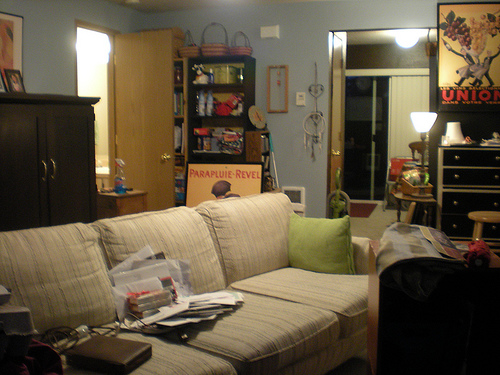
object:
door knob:
[161, 153, 171, 162]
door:
[113, 27, 175, 215]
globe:
[393, 37, 418, 47]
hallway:
[319, 27, 437, 215]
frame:
[3, 65, 26, 93]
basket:
[177, 29, 201, 57]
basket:
[199, 21, 230, 60]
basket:
[228, 30, 252, 56]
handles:
[37, 158, 57, 183]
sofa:
[0, 192, 417, 375]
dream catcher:
[301, 58, 325, 159]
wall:
[131, 1, 441, 213]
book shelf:
[184, 56, 255, 174]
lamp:
[408, 108, 440, 198]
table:
[391, 191, 438, 235]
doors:
[0, 87, 102, 249]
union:
[442, 87, 499, 102]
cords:
[47, 315, 188, 344]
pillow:
[288, 211, 354, 271]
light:
[74, 27, 111, 64]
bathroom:
[75, 21, 113, 188]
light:
[393, 28, 423, 49]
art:
[431, 0, 498, 107]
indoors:
[0, 4, 499, 375]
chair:
[469, 209, 499, 245]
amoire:
[0, 91, 102, 243]